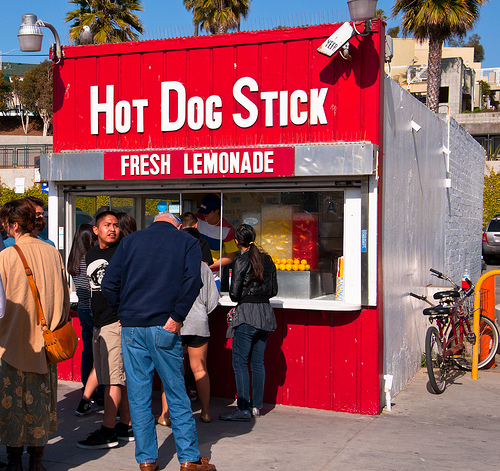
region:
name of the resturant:
[68, 42, 373, 159]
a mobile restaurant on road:
[44, 33, 471, 413]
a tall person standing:
[115, 216, 213, 468]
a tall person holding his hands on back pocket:
[100, 207, 222, 462]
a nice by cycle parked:
[407, 264, 499, 419]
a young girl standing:
[234, 222, 287, 460]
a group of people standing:
[13, 168, 341, 461]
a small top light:
[10, 7, 73, 74]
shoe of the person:
[172, 449, 201, 467]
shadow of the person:
[191, 397, 266, 456]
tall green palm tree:
[395, 5, 469, 119]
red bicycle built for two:
[397, 261, 497, 393]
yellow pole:
[466, 283, 494, 389]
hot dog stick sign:
[70, 71, 385, 140]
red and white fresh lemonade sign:
[93, 151, 303, 181]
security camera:
[300, 19, 368, 84]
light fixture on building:
[10, 14, 82, 68]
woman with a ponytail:
[219, 215, 286, 435]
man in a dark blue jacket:
[100, 198, 221, 463]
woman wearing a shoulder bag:
[3, 193, 93, 448]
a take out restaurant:
[47, 21, 482, 409]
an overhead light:
[20, 15, 57, 67]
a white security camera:
[307, 24, 367, 74]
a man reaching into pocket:
[106, 212, 211, 467]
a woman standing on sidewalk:
[228, 222, 273, 424]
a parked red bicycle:
[419, 256, 494, 396]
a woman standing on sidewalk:
[0, 199, 62, 464]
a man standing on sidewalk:
[84, 215, 135, 450]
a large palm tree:
[394, 0, 471, 105]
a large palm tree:
[183, 0, 247, 34]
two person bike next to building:
[416, 270, 486, 405]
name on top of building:
[65, 64, 342, 139]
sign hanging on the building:
[99, 149, 314, 179]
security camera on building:
[297, 27, 379, 72]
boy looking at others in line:
[86, 211, 133, 288]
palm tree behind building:
[407, 0, 496, 128]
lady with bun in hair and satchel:
[2, 209, 74, 362]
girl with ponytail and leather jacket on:
[224, 220, 304, 425]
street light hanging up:
[11, 11, 67, 71]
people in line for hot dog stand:
[0, 51, 347, 446]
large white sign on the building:
[80, 72, 357, 138]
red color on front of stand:
[45, 29, 394, 139]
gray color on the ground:
[295, 423, 411, 454]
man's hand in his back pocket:
[145, 312, 211, 354]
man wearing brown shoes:
[170, 444, 216, 467]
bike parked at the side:
[410, 261, 489, 374]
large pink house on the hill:
[411, 33, 478, 110]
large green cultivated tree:
[20, 56, 72, 116]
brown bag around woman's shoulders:
[17, 285, 97, 385]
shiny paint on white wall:
[407, 193, 445, 279]